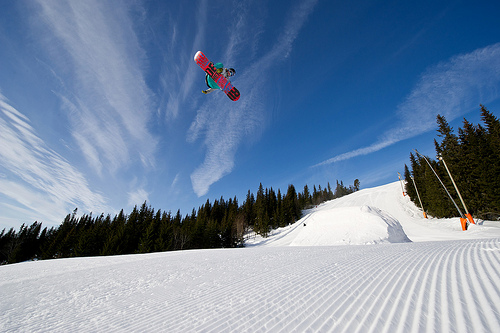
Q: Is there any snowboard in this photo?
A: Yes, there is a snowboard.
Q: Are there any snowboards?
A: Yes, there is a snowboard.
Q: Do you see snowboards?
A: Yes, there is a snowboard.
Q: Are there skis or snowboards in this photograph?
A: Yes, there is a snowboard.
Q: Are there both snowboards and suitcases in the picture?
A: No, there is a snowboard but no suitcases.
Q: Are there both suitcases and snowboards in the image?
A: No, there is a snowboard but no suitcases.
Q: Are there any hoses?
A: No, there are no hoses.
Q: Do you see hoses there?
A: No, there are no hoses.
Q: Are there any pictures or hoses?
A: No, there are no hoses or pictures.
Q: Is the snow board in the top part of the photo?
A: Yes, the snow board is in the top of the image.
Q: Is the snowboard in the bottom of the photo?
A: No, the snowboard is in the top of the image.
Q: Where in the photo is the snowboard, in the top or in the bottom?
A: The snowboard is in the top of the image.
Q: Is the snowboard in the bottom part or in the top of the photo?
A: The snowboard is in the top of the image.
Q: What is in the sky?
A: The snowboard is in the sky.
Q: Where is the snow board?
A: The snow board is in the sky.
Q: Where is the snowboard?
A: The snow board is in the sky.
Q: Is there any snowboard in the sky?
A: Yes, there is a snowboard in the sky.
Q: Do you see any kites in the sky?
A: No, there is a snowboard in the sky.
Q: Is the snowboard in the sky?
A: Yes, the snowboard is in the sky.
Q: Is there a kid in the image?
A: No, there are no children.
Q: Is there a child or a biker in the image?
A: No, there are no children or bikers.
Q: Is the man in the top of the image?
A: Yes, the man is in the top of the image.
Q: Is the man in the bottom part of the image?
A: No, the man is in the top of the image.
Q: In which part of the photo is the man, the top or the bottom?
A: The man is in the top of the image.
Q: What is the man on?
A: The man is on the snowboard.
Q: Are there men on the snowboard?
A: Yes, there is a man on the snowboard.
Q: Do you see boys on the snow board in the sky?
A: No, there is a man on the snowboard.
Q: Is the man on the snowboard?
A: Yes, the man is on the snowboard.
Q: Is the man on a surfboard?
A: No, the man is on the snowboard.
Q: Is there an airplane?
A: No, there are no airplanes.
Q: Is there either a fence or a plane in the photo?
A: No, there are no airplanes or fences.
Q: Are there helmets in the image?
A: No, there are no helmets.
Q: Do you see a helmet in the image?
A: No, there are no helmets.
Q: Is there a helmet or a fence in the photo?
A: No, there are no helmets or fences.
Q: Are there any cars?
A: No, there are no cars.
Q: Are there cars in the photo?
A: No, there are no cars.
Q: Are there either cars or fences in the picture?
A: No, there are no cars or fences.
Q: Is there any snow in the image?
A: Yes, there is snow.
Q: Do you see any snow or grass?
A: Yes, there is snow.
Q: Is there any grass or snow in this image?
A: Yes, there is snow.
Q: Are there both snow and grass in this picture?
A: No, there is snow but no grass.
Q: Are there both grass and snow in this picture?
A: No, there is snow but no grass.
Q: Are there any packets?
A: No, there are no packets.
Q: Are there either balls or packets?
A: No, there are no packets or balls.